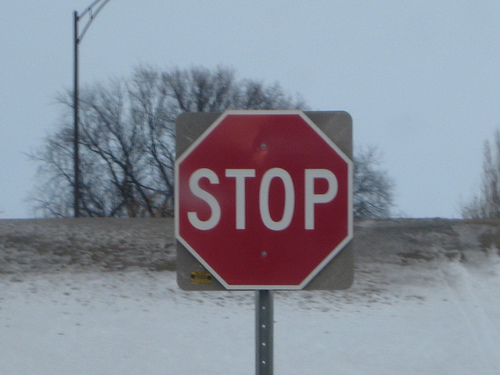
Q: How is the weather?
A: It is clear.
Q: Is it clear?
A: Yes, it is clear.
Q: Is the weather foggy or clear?
A: It is clear.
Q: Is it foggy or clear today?
A: It is clear.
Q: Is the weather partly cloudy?
A: No, it is clear.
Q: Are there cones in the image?
A: No, there are no cones.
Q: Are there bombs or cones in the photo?
A: No, there are no cones or bombs.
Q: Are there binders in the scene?
A: No, there are no binders.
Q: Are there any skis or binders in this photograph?
A: No, there are no binders or skis.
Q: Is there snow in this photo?
A: Yes, there is snow.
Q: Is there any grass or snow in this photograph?
A: Yes, there is snow.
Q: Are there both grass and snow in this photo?
A: Yes, there are both snow and grass.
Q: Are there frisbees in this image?
A: No, there are no frisbees.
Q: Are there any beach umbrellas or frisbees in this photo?
A: No, there are no frisbees or beach umbrellas.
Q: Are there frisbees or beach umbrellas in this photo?
A: No, there are no frisbees or beach umbrellas.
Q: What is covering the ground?
A: The snow is covering the ground.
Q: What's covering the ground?
A: The snow is covering the ground.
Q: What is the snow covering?
A: The snow is covering the ground.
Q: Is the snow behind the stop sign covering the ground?
A: Yes, the snow is covering the ground.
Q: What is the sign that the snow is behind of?
A: The sign is a stop sign.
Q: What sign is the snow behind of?
A: The snow is behind the stop sign.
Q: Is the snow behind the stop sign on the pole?
A: Yes, the snow is behind the stop sign.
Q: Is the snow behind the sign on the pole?
A: Yes, the snow is behind the stop sign.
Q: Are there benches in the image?
A: No, there are no benches.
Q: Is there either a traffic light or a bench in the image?
A: No, there are no benches or traffic lights.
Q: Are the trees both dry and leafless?
A: Yes, the trees are dry and leafless.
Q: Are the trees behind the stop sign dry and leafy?
A: No, the trees are dry but leafless.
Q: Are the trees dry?
A: Yes, the trees are dry.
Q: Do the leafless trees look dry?
A: Yes, the trees are dry.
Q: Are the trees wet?
A: No, the trees are dry.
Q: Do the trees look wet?
A: No, the trees are dry.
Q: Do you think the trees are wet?
A: No, the trees are dry.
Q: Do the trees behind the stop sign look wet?
A: No, the trees are dry.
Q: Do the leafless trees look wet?
A: No, the trees are dry.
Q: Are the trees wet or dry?
A: The trees are dry.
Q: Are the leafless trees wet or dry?
A: The trees are dry.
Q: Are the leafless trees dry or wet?
A: The trees are dry.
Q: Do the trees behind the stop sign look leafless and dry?
A: Yes, the trees are leafless and dry.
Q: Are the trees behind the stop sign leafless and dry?
A: Yes, the trees are leafless and dry.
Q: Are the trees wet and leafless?
A: No, the trees are leafless but dry.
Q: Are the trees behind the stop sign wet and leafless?
A: No, the trees are leafless but dry.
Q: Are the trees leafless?
A: Yes, the trees are leafless.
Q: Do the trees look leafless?
A: Yes, the trees are leafless.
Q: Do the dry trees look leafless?
A: Yes, the trees are leafless.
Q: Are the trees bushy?
A: No, the trees are leafless.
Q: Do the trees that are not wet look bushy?
A: No, the trees are leafless.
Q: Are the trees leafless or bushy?
A: The trees are leafless.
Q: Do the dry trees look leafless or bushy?
A: The trees are leafless.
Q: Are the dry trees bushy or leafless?
A: The trees are leafless.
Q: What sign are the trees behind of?
A: The trees are behind the stop sign.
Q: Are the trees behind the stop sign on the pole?
A: Yes, the trees are behind the stop sign.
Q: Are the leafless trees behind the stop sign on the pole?
A: Yes, the trees are behind the stop sign.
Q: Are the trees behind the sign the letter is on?
A: Yes, the trees are behind the stop sign.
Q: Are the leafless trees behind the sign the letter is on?
A: Yes, the trees are behind the stop sign.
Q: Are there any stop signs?
A: Yes, there is a stop sign.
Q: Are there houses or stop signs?
A: Yes, there is a stop sign.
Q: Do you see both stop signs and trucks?
A: No, there is a stop sign but no trucks.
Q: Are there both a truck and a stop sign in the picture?
A: No, there is a stop sign but no trucks.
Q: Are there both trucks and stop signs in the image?
A: No, there is a stop sign but no trucks.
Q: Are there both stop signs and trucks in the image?
A: No, there is a stop sign but no trucks.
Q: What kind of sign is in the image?
A: The sign is a stop sign.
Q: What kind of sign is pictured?
A: The sign is a stop sign.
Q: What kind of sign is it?
A: The sign is a stop sign.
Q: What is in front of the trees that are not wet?
A: The stop sign is in front of the trees.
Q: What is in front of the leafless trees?
A: The stop sign is in front of the trees.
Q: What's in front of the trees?
A: The stop sign is in front of the trees.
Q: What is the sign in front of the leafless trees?
A: The sign is a stop sign.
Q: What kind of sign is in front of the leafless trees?
A: The sign is a stop sign.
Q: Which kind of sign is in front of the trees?
A: The sign is a stop sign.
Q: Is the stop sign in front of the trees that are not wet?
A: Yes, the stop sign is in front of the trees.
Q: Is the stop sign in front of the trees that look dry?
A: Yes, the stop sign is in front of the trees.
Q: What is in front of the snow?
A: The stop sign is in front of the snow.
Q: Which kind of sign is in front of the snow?
A: The sign is a stop sign.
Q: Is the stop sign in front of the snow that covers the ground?
A: Yes, the stop sign is in front of the snow.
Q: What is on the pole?
A: The stop sign is on the pole.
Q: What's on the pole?
A: The stop sign is on the pole.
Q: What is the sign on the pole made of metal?
A: The sign is a stop sign.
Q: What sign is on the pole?
A: The sign is a stop sign.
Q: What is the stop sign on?
A: The stop sign is on the pole.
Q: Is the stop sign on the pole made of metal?
A: Yes, the stop sign is on the pole.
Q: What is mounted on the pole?
A: The stop sign is mounted on the pole.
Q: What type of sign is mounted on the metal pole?
A: The sign is a stop sign.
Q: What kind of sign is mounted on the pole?
A: The sign is a stop sign.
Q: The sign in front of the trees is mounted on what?
A: The stop sign is mounted on the pole.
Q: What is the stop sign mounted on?
A: The stop sign is mounted on the pole.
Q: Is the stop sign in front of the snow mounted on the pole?
A: Yes, the stop sign is mounted on the pole.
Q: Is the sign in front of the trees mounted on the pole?
A: Yes, the stop sign is mounted on the pole.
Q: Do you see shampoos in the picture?
A: No, there are no shampoos.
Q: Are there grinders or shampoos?
A: No, there are no shampoos or grinders.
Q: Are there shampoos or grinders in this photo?
A: No, there are no shampoos or grinders.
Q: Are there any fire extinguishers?
A: No, there are no fire extinguishers.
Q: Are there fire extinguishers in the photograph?
A: No, there are no fire extinguishers.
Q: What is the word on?
A: The word is on the stop sign.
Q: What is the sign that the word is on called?
A: The sign is a stop sign.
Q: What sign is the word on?
A: The word is on the stop sign.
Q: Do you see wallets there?
A: No, there are no wallets.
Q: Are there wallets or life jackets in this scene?
A: No, there are no wallets or life jackets.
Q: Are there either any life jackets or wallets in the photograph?
A: No, there are no wallets or life jackets.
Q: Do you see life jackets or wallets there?
A: No, there are no wallets or life jackets.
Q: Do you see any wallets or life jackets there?
A: No, there are no wallets or life jackets.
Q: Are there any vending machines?
A: No, there are no vending machines.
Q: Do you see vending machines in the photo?
A: No, there are no vending machines.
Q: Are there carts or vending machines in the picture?
A: No, there are no vending machines or carts.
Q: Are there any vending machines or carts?
A: No, there are no vending machines or carts.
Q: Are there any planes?
A: No, there are no planes.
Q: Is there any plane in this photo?
A: No, there are no airplanes.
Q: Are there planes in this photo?
A: No, there are no planes.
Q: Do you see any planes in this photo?
A: No, there are no planes.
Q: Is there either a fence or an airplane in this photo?
A: No, there are no airplanes or fences.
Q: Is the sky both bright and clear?
A: Yes, the sky is bright and clear.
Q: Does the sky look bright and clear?
A: Yes, the sky is bright and clear.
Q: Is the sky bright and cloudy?
A: No, the sky is bright but clear.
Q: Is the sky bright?
A: Yes, the sky is bright.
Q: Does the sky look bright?
A: Yes, the sky is bright.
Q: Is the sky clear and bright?
A: Yes, the sky is clear and bright.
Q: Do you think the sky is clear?
A: Yes, the sky is clear.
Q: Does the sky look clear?
A: Yes, the sky is clear.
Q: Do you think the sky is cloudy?
A: No, the sky is clear.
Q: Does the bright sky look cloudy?
A: No, the sky is clear.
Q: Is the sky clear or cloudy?
A: The sky is clear.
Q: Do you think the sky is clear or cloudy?
A: The sky is clear.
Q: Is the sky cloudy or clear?
A: The sky is clear.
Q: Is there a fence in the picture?
A: No, there are no fences.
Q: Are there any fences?
A: No, there are no fences.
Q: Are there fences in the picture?
A: No, there are no fences.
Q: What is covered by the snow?
A: The ground is covered by the snow.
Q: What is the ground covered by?
A: The ground is covered by the snow.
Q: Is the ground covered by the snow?
A: Yes, the ground is covered by the snow.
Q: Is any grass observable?
A: Yes, there is grass.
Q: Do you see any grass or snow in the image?
A: Yes, there is grass.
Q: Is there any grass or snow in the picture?
A: Yes, there is grass.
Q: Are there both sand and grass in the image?
A: No, there is grass but no sand.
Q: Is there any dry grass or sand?
A: Yes, there is dry grass.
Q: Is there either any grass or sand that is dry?
A: Yes, the grass is dry.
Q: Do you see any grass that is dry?
A: Yes, there is dry grass.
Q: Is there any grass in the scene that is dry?
A: Yes, there is grass that is dry.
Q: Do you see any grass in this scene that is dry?
A: Yes, there is grass that is dry.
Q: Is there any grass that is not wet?
A: Yes, there is dry grass.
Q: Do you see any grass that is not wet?
A: Yes, there is dry grass.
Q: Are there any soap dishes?
A: No, there are no soap dishes.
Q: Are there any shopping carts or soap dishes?
A: No, there are no soap dishes or shopping carts.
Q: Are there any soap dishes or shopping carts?
A: No, there are no soap dishes or shopping carts.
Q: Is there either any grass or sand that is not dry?
A: No, there is grass but it is dry.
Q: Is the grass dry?
A: Yes, the grass is dry.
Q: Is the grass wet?
A: No, the grass is dry.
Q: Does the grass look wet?
A: No, the grass is dry.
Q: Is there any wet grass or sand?
A: No, there is grass but it is dry.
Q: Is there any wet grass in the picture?
A: No, there is grass but it is dry.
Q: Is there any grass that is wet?
A: No, there is grass but it is dry.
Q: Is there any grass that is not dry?
A: No, there is grass but it is dry.